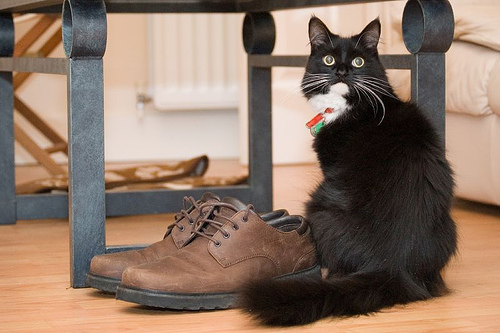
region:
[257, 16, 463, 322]
black cat on floor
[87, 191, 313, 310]
brown shoes on floor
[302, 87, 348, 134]
black cat has white toy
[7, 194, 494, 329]
hardwood floor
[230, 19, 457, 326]
black cat on hardwood floor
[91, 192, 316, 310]
pair of brown shoes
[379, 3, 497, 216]
cream colored couch behind cat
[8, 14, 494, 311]
cat and shoes under metal table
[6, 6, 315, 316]
shoes under metal table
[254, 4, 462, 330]
black cat under metal table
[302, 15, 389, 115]
surprised look on a cat's face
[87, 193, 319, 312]
a pair of brown shoes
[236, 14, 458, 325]
a black cat with a bit of white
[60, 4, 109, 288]
a metal leg of a table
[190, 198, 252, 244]
brown shoestring on a shoe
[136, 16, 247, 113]
a radio on the wall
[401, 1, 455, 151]
a metal leg of a table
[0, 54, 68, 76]
a cross brace of the table legs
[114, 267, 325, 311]
rubber sole on a brown shoe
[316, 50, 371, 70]
a wide-eyed cat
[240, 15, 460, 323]
a black and white cat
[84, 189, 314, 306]
two dark brown shoes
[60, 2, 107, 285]
a black metal chair leg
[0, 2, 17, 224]
a black metal chair leg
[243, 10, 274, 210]
a black metal chair leg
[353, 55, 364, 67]
eye of a cat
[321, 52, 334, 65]
eye of a cat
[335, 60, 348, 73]
nose of a cat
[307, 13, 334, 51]
ear of a cat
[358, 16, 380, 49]
ear of a cat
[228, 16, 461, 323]
black and white house cat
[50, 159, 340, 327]
brown, leather shoes of an adult male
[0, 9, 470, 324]
metal chair legs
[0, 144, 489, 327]
real wood flooring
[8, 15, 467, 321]
bedroom scene as seen from under a metal chair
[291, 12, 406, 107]
the beautiful yellow eyes of a cat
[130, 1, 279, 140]
white radiator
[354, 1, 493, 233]
white sofa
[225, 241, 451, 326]
the tail of a black cat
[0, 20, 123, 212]
the legs of a wooden chair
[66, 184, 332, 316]
brown shoes for a man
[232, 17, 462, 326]
a black cat with white fur on it's neck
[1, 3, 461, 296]
a metal structure behind the cat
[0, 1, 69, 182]
a wooden structure to the left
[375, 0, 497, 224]
a beige sofa on the right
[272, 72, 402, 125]
white whiskers on the cat's face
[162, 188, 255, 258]
the shoelaces are untied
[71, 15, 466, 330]
brown shoes next to a cat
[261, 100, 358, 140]
part of the cat's collar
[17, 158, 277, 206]
a rolled up rug